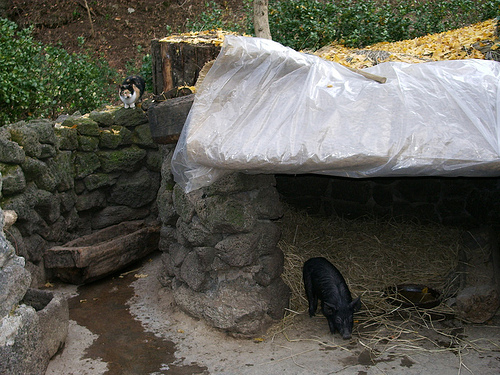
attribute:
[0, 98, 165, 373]
wall — stone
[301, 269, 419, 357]
boar — black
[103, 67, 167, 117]
cat — brown white and black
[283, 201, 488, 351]
hay — yellow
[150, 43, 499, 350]
cave — stone, plastic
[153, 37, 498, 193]
covering — plastic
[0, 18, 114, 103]
bush — green leaves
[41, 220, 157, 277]
water basin — stone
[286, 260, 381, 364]
boar — black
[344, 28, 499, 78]
leaves — yellow, dried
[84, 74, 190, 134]
black cat — white, orange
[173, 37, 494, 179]
tarp — plastic, white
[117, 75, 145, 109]
cat — furry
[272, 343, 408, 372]
floor — cement